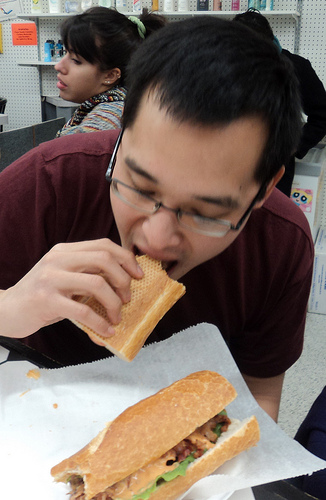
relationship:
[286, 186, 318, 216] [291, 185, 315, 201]
cartoon has hair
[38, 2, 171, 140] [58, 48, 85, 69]
woman has eyes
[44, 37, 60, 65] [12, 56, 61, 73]
toiletry on top of shelf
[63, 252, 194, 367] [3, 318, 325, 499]
sandwich on top of paper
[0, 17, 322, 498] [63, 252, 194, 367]
man holding sandwich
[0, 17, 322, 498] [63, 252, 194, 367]
man biting sandwich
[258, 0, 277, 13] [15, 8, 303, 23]
bottle on top of shelf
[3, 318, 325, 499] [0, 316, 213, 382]
paper has edge